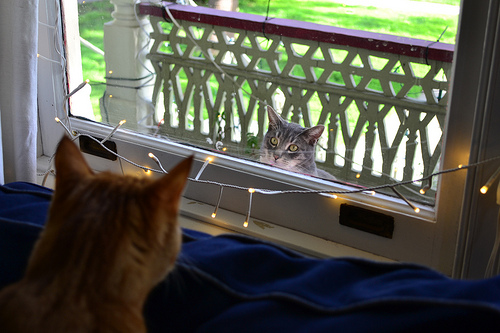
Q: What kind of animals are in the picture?
A: Cats.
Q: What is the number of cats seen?
A: 2.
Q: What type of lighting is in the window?
A: Holiday lights.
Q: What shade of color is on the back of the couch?
A: Dark blue.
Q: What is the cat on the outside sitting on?
A: A porch.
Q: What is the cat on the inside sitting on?
A: The back of the sofa.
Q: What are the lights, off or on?
A: On.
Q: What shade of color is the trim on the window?
A: White.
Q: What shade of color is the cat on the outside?
A: Grey.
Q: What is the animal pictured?
A: House cats.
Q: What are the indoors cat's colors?
A: Orange tabby.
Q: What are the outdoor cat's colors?
A: Gray and white.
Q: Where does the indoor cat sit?
A: On a blue sofa.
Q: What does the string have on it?
A: Lights.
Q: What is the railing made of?
A: Wood.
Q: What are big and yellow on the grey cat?
A: Eyes.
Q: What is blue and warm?
A: The blanket.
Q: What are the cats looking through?
A: The window.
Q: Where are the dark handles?
A: On the window.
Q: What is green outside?
A: The grass.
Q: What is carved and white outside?
A: The pillar.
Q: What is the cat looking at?
A: Another cat.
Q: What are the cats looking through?
A: The window.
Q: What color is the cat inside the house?
A: Orange.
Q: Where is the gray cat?
A: Porch.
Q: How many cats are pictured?
A: 2.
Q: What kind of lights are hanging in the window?
A: Christmas.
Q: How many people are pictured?
A: 0.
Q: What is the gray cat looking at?
A: Orange cat.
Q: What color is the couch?
A: Blue.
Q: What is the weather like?
A: Sunny.